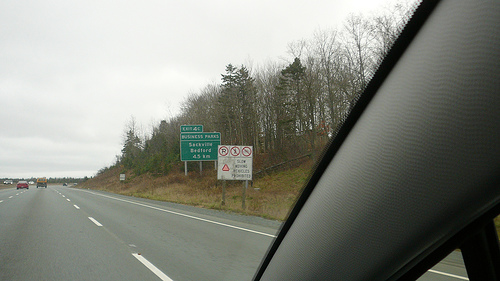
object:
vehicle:
[17, 181, 31, 191]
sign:
[117, 174, 125, 181]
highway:
[0, 172, 468, 279]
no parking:
[220, 146, 229, 156]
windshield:
[1, 2, 436, 279]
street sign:
[215, 145, 255, 179]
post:
[242, 180, 247, 209]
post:
[222, 176, 226, 210]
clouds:
[14, 8, 218, 152]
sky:
[0, 0, 420, 177]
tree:
[270, 55, 325, 170]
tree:
[211, 56, 247, 176]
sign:
[178, 120, 223, 162]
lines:
[56, 187, 171, 278]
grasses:
[0, 0, 350, 275]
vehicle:
[163, 89, 500, 281]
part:
[271, 184, 416, 281]